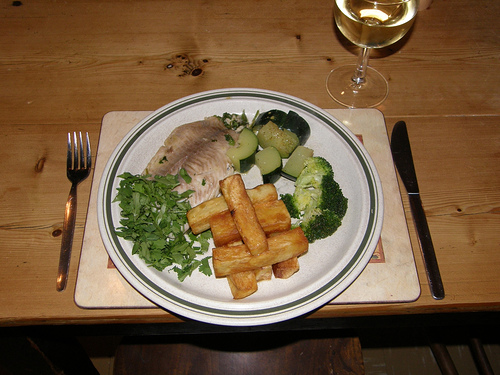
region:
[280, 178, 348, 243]
cooked green broccoli crowns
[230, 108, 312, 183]
Soft green cooked zucchini chunks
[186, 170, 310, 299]
Wide cut golden brown french fries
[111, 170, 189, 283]
Finely chopped slightly wilted cilantro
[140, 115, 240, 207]
baked fish filet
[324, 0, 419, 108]
partially full glass of white wine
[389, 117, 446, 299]
slightly scuffed butter knife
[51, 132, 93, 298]
steel silverware fork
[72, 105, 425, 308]
large brown place mat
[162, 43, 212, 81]
knot in wood table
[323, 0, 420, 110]
clear glass wine glass with wine in it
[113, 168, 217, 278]
pile of chopped cilantro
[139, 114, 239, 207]
baked filet of fish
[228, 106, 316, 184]
chunks of cooked zucchini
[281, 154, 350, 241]
serving of broccoli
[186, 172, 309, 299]
cut french fried potatoes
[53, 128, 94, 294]
silver metal fork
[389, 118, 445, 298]
silver metal knife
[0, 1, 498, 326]
light wood table top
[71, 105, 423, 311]
light tan place mat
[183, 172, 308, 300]
a stack of sliced potatoes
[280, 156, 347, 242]
a few broccoli florets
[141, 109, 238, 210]
a piece of baked fish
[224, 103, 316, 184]
slices of zucchini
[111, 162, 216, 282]
finely chopped greens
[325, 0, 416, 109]
a glass of white wine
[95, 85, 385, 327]
a white plate with a green rim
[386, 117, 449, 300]
a butter knife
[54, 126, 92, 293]
a fork on the table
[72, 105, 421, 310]
a rectangular place mat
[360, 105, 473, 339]
The knife is on the right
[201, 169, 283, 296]
The fries are golden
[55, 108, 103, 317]
The fork is on the left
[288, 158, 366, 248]
The broccoli is green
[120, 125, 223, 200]
The fish is on the plate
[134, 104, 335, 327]
The plate is white with green stripes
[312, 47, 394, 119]
The bottom of the glass is clear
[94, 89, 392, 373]
The plate is on a placemat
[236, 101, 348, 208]
The vegetables are cooked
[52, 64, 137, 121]
The table is wooden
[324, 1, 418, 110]
a wine glass on a table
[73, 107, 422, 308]
a placemat on a table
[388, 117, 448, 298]
a knife next to a placemat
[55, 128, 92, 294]
a fork next to a placemat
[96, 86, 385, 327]
a white plate with a green ring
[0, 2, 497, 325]
a wood table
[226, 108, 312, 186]
zucchini on a plate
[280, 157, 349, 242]
broccoli on a plate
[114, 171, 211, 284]
chopped parsley on a plate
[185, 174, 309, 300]
blocks of potato on a plate